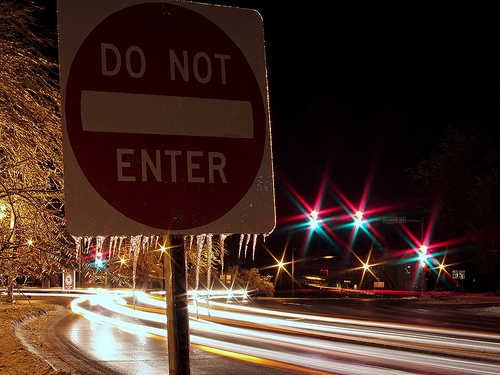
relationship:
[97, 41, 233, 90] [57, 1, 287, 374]
text on sign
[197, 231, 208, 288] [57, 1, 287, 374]
icicle on sign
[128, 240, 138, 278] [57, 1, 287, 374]
icicle on sign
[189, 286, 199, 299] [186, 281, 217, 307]
headlight on car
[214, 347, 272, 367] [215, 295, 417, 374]
line on road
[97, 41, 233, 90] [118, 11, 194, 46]
text on circle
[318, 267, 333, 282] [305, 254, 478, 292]
window in building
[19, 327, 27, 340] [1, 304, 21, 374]
snow on ground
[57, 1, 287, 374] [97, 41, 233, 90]
sign has text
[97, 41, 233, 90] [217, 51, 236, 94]
text has letter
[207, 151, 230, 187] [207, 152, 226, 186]
text has letter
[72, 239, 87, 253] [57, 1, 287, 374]
icicle on sign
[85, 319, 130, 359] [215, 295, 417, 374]
reflection on road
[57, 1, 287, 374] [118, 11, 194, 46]
sign has circle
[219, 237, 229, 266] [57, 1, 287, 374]
icicle on sign